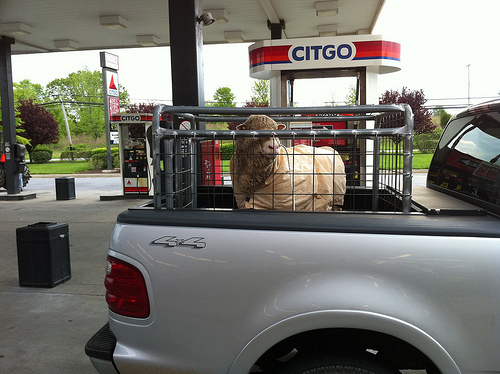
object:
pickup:
[82, 99, 499, 373]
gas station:
[0, 1, 402, 373]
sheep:
[227, 114, 345, 213]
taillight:
[103, 254, 150, 318]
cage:
[151, 104, 414, 214]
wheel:
[262, 335, 421, 372]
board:
[103, 53, 119, 70]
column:
[168, 0, 203, 187]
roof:
[1, 0, 385, 55]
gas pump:
[248, 35, 401, 190]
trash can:
[15, 221, 73, 288]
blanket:
[230, 145, 348, 214]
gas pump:
[109, 113, 153, 196]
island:
[98, 190, 154, 202]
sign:
[106, 70, 120, 97]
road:
[21, 172, 429, 191]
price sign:
[109, 97, 120, 115]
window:
[430, 102, 498, 202]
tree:
[15, 99, 57, 168]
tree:
[375, 86, 437, 144]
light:
[223, 30, 247, 44]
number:
[181, 237, 207, 248]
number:
[153, 235, 179, 246]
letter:
[338, 44, 353, 61]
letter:
[321, 44, 336, 61]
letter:
[311, 45, 323, 61]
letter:
[303, 45, 311, 60]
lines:
[351, 40, 402, 59]